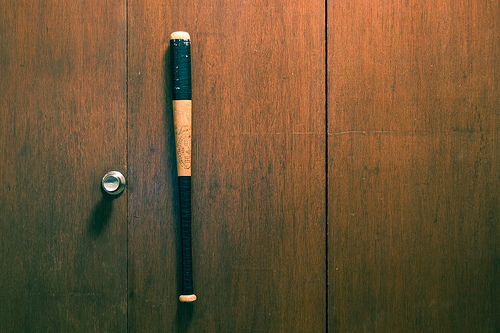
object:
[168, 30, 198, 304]
baseball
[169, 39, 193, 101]
tape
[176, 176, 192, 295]
grip tape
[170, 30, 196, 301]
bat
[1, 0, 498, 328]
table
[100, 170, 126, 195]
object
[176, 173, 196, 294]
tape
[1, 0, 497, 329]
wall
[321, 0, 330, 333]
seam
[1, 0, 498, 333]
wood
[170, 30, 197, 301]
wood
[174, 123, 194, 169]
stamp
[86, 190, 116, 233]
shadow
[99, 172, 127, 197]
door knob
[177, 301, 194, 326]
shadow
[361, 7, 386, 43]
specks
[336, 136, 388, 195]
specks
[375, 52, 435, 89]
specks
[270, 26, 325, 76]
specks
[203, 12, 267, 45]
specks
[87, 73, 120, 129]
specks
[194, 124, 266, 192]
specks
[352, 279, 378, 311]
strike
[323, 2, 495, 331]
door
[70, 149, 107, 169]
strike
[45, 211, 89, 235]
strike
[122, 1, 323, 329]
door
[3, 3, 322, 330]
door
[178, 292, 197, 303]
knob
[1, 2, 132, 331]
door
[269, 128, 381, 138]
scuff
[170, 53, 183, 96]
specs